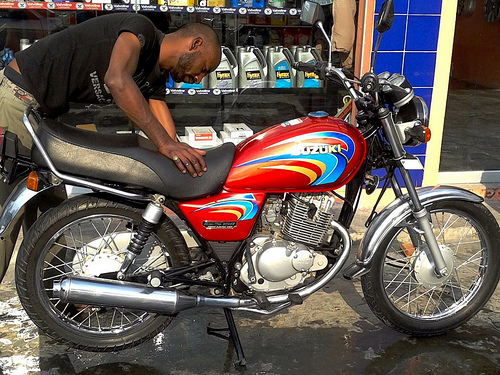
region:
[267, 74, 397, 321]
this is a motorbike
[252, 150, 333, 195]
the motorbike is red in color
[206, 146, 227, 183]
this is a seat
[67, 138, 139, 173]
the seat is leather like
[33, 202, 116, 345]
this is a wheel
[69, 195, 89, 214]
the wheel is black in color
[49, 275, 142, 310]
this is the exhause pipe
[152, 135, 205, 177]
the hand is on the seat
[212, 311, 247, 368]
this is a stand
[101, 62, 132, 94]
the elbow is bent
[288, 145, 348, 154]
Manufacturer emblem on fuel tank of motorcycle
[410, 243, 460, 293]
Drum style brakes on front wheel of motorcycle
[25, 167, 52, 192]
Rear turn signal on motorcycle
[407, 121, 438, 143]
Front turn signal on motorcycle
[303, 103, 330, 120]
Filler cap on motorcycle fuel tank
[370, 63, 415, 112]
Instrument cluster for motorcycle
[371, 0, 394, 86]
Rearview mirror attached to motorcycle handlebar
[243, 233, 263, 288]
Kick starter to start motorcycle engine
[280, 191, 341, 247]
Cooling fins on cylinder of motorcycle engine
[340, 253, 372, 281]
Splash guard on motorcycle fender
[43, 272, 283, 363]
the pipe is silver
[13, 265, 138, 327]
the pipe is silver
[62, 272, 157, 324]
the pipe is silver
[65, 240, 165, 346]
the pipe is silver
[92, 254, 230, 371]
the pipe is silver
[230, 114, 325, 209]
the tank is red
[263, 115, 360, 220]
the tank is red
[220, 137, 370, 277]
the tank is red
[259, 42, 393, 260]
the tank is red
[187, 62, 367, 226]
the tank is red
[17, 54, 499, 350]
a colorful red motorcycle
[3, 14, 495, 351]
a man bent over a motorcycle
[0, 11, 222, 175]
a man wearing a black t-shirt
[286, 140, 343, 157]
printed corporate motorcycle logo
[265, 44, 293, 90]
a bottle of automotive fluid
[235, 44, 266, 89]
a bottle of automotive fluid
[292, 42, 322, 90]
a bottle of automotive fluid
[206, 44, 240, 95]
a bottle of automotive fluid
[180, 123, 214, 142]
a white box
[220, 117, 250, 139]
a white box